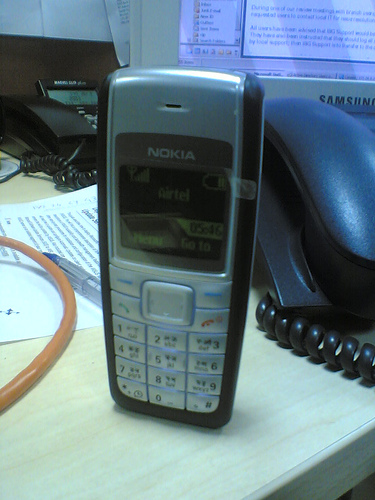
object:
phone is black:
[0, 78, 101, 191]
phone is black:
[254, 91, 375, 388]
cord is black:
[254, 291, 375, 384]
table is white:
[0, 135, 375, 499]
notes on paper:
[12, 209, 114, 288]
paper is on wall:
[102, 1, 132, 70]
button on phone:
[112, 313, 147, 345]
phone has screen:
[118, 165, 232, 277]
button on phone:
[188, 332, 229, 355]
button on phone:
[146, 345, 187, 372]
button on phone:
[185, 392, 220, 414]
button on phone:
[147, 384, 186, 411]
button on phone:
[116, 375, 148, 403]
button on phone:
[115, 355, 147, 384]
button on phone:
[147, 325, 188, 352]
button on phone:
[187, 352, 226, 376]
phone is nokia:
[147, 147, 195, 162]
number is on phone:
[155, 374, 161, 384]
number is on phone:
[209, 382, 217, 391]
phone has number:
[211, 361, 218, 370]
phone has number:
[117, 323, 122, 333]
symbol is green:
[118, 302, 130, 314]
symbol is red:
[201, 318, 215, 327]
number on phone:
[154, 334, 161, 345]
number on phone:
[212, 341, 220, 350]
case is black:
[109, 384, 233, 431]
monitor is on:
[127, 0, 375, 104]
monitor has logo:
[319, 94, 374, 106]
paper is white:
[0, 180, 161, 346]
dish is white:
[0, 155, 22, 185]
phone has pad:
[107, 262, 235, 415]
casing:
[218, 70, 267, 432]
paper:
[0, 181, 105, 345]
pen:
[42, 250, 103, 308]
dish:
[0, 149, 19, 183]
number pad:
[112, 313, 229, 415]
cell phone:
[96, 66, 267, 430]